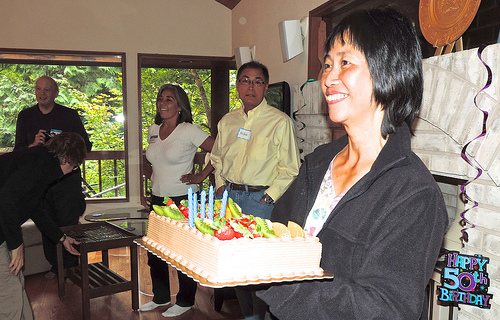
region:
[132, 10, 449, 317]
woman carrying a rectangle birthday cake with candles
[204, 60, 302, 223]
man wearing blue jeans and a yellow long sleeve shirt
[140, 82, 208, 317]
woman wearing dark pants and a white short sleeve shirt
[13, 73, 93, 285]
bald man wearing all black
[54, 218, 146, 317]
black table with two shelves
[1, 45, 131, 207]
large picture window with a blind on it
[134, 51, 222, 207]
window with a brown wooden frame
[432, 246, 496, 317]
Happy 50th Birthday sign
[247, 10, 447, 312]
woman with dark gray jacket and black hair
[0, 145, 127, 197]
outdoor deck or railing on a stairway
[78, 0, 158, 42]
a light beige wall.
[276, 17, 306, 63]
a white birthday card on the wall.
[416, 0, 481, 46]
a orange decoration plate.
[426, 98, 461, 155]
a piece of white and grey decoration paper.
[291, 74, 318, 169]
a long green and purple ribbon.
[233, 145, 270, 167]
a man is wearing a yellow shirt.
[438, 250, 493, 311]
a happy 50th birthday decoration.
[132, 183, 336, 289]
a big orange birthday cake with candles.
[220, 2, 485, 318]
this is a woman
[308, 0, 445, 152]
black hair on woman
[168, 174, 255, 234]
blue candles on cake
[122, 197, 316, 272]
tan icing on cake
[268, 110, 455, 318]
woman wearing black jacket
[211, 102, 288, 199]
man wearing a yellow shirt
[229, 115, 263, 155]
man wearing a name tag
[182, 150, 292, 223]
man has hands in pocket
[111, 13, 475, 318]
woman holding a cake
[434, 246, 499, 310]
black, blue, and purple decoration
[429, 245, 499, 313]
50th birthday decoration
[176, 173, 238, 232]
five blue candles on the cake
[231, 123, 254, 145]
name tag on the shirt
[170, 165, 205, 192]
hand on the hip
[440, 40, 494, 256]
curly purple ribbon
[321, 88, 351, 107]
big smile on the face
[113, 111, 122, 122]
light glare on the glass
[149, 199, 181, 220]
green fruit on top of the cake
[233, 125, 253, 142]
blue and white name tag on the yellow shirt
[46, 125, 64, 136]
blue and white name tag on the black shirt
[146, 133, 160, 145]
name tag on the white shirt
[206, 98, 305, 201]
yellow shirt on the man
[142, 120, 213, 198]
white shirt on the woman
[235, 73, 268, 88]
glasses on the man's face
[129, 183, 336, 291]
white cake in the woman's hands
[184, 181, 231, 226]
blue candles on the cake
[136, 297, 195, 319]
white socks on the woman's feet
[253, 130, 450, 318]
black jacket on the woman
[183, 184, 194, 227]
blue candle on top of a cake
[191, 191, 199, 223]
blue candle on top of a cake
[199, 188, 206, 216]
blue candle on top of a cake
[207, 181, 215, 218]
blue candle on top of a cake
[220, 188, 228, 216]
blue candle on top of a cake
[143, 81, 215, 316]
woman wearing short sleeved white tee shirt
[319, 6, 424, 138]
woman with black shiny hair smiling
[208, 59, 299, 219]
man wearing yellow long sleeved shirt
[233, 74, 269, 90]
black rimmed glasses with light reflection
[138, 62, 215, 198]
a window on a building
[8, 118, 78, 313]
a person is standing up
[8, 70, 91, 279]
a person is standing up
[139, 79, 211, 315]
a person is standing up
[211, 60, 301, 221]
a person is standing up